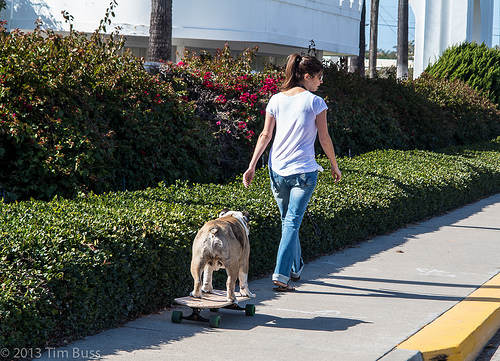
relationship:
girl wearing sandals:
[242, 52, 341, 292] [272, 268, 302, 292]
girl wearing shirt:
[242, 52, 341, 292] [265, 91, 327, 175]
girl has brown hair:
[242, 52, 341, 292] [276, 42, 329, 89]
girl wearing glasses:
[242, 52, 341, 292] [310, 70, 326, 82]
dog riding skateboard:
[195, 194, 291, 290] [169, 285, 256, 328]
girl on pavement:
[242, 52, 341, 292] [2, 180, 499, 360]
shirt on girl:
[265, 91, 327, 175] [242, 52, 341, 292]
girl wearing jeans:
[242, 52, 341, 292] [269, 168, 318, 285]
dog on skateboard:
[188, 210, 252, 303] [169, 289, 251, 324]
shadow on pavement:
[219, 313, 373, 332] [45, 197, 497, 359]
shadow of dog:
[223, 302, 374, 339] [173, 211, 261, 306]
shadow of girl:
[297, 264, 484, 301] [228, 26, 380, 335]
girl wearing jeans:
[240, 52, 345, 292] [273, 169, 325, 287]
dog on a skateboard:
[188, 210, 252, 303] [168, 292, 259, 327]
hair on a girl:
[280, 50, 329, 90] [242, 52, 341, 292]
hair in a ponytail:
[279, 52, 324, 91] [276, 47, 306, 89]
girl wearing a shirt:
[242, 52, 341, 292] [265, 90, 329, 177]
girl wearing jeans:
[242, 52, 341, 292] [273, 150, 356, 322]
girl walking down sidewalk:
[242, 52, 341, 292] [36, 194, 498, 356]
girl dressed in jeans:
[242, 52, 341, 292] [269, 168, 314, 284]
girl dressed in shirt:
[242, 52, 341, 292] [265, 90, 329, 177]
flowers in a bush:
[167, 37, 274, 150] [6, 144, 498, 358]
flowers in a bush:
[167, 60, 280, 139] [6, 144, 498, 358]